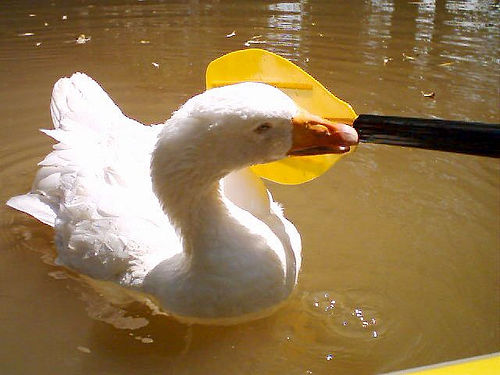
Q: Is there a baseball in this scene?
A: No, there are no baseballs.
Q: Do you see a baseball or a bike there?
A: No, there are no baseballs or bikes.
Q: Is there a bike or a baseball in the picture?
A: No, there are no baseballs or bikes.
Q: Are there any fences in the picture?
A: No, there are no fences.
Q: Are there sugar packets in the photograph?
A: No, there are no sugar packets.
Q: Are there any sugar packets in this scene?
A: No, there are no sugar packets.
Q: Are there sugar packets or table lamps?
A: No, there are no sugar packets or table lamps.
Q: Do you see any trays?
A: No, there are no trays.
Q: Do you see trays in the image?
A: No, there are no trays.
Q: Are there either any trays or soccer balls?
A: No, there are no trays or soccer balls.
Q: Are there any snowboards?
A: No, there are no snowboards.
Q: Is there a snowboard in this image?
A: No, there are no snowboards.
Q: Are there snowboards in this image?
A: No, there are no snowboards.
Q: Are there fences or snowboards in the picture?
A: No, there are no snowboards or fences.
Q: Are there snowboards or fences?
A: No, there are no snowboards or fences.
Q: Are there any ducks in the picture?
A: Yes, there is a duck.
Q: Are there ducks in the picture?
A: Yes, there is a duck.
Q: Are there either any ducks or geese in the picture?
A: Yes, there is a duck.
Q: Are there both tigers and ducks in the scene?
A: No, there is a duck but no tigers.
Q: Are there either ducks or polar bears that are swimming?
A: Yes, the duck is swimming.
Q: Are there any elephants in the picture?
A: No, there are no elephants.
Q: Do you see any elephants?
A: No, there are no elephants.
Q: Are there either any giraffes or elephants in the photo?
A: No, there are no elephants or giraffes.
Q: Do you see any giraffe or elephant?
A: No, there are no elephants or giraffes.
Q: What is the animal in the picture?
A: The animal is a duck.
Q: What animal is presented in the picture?
A: The animal is a duck.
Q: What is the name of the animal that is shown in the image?
A: The animal is a duck.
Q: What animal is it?
A: The animal is a duck.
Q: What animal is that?
A: This is a duck.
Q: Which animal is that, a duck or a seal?
A: This is a duck.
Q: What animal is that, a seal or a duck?
A: This is a duck.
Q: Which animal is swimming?
A: The animal is a duck.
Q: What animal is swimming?
A: The animal is a duck.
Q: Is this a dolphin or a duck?
A: This is a duck.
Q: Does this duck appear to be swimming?
A: Yes, the duck is swimming.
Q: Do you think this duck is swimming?
A: Yes, the duck is swimming.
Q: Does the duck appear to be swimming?
A: Yes, the duck is swimming.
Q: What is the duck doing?
A: The duck is swimming.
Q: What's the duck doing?
A: The duck is swimming.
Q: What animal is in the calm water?
A: The duck is in the water.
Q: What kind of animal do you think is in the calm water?
A: The animal is a duck.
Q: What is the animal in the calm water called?
A: The animal is a duck.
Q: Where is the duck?
A: The duck is in the water.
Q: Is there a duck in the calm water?
A: Yes, there is a duck in the water.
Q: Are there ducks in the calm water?
A: Yes, there is a duck in the water.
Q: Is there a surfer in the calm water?
A: No, there is a duck in the water.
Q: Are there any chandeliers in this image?
A: No, there are no chandeliers.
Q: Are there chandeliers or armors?
A: No, there are no chandeliers or armors.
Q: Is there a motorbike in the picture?
A: No, there are no motorcycles.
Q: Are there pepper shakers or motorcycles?
A: No, there are no motorcycles or pepper shakers.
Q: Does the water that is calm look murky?
A: Yes, the water is murky.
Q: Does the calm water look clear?
A: No, the water is murky.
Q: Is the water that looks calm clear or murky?
A: The water is murky.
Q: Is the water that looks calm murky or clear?
A: The water is murky.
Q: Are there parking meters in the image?
A: No, there are no parking meters.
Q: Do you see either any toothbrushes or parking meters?
A: No, there are no parking meters or toothbrushes.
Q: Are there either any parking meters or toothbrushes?
A: No, there are no parking meters or toothbrushes.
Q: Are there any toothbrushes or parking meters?
A: No, there are no parking meters or toothbrushes.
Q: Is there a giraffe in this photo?
A: No, there are no giraffes.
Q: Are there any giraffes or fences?
A: No, there are no giraffes or fences.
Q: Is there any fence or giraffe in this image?
A: No, there are no giraffes or fences.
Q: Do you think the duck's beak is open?
A: Yes, the beak is open.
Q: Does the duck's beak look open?
A: Yes, the beak is open.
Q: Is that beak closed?
A: No, the beak is open.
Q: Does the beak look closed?
A: No, the beak is open.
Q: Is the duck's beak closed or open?
A: The beak is open.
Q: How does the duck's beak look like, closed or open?
A: The beak is open.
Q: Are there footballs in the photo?
A: No, there are no footballs.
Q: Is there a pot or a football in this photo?
A: No, there are no footballs or pots.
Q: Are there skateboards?
A: No, there are no skateboards.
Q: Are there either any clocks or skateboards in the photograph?
A: No, there are no skateboards or clocks.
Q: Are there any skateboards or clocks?
A: No, there are no skateboards or clocks.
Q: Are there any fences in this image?
A: No, there are no fences.